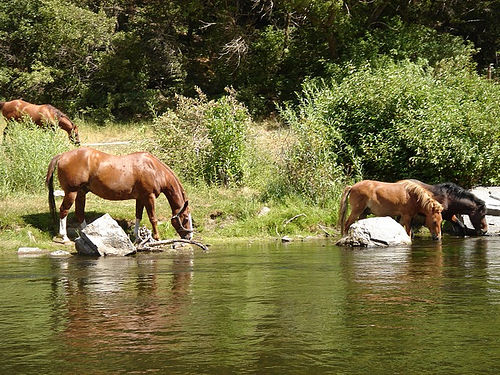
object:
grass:
[5, 103, 331, 250]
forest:
[0, 0, 497, 232]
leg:
[72, 187, 87, 227]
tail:
[44, 152, 61, 229]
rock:
[74, 212, 137, 255]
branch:
[134, 226, 206, 251]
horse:
[45, 146, 194, 241]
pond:
[40, 225, 455, 346]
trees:
[88, 27, 190, 117]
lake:
[2, 251, 497, 373]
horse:
[393, 175, 486, 246]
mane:
[440, 183, 480, 203]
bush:
[129, 84, 257, 186]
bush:
[271, 50, 497, 207]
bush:
[0, 112, 80, 194]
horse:
[0, 97, 81, 149]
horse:
[334, 180, 444, 243]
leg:
[57, 190, 77, 243]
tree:
[0, 1, 133, 118]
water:
[0, 242, 485, 372]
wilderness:
[0, 0, 500, 373]